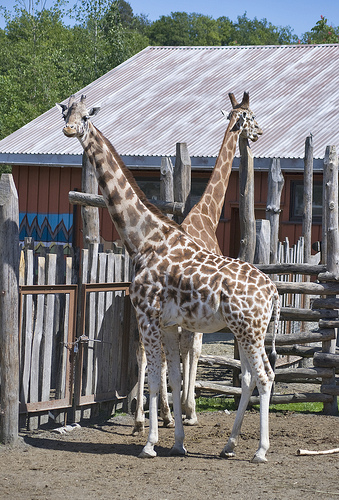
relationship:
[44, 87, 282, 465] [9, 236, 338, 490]
giraffe in enclosure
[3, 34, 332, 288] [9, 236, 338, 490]
building next to enclosure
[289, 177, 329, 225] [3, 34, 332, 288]
window in building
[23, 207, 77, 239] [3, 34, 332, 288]
painting on side building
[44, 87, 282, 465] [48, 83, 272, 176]
giraffes facing opposite directions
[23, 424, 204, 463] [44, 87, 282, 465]
shadow of a giraffe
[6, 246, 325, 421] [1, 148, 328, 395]
fence made of logs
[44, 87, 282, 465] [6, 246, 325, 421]
giraffe standing by fence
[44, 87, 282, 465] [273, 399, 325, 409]
giraffe looking for food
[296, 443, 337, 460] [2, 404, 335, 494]
stick on ground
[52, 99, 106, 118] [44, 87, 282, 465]
ears of a giraffe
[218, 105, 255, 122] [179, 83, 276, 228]
ears of a giraffe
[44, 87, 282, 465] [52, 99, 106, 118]
giraffe has ears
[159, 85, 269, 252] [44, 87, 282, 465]
giraffe standing next to giraffe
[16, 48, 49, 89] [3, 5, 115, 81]
leaves on trees